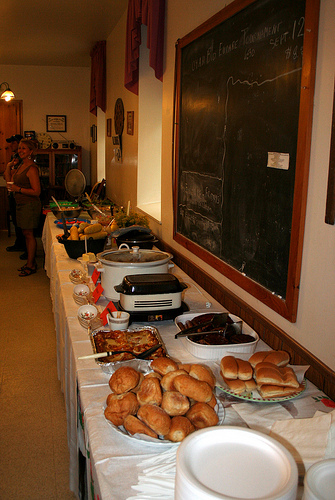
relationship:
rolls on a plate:
[104, 354, 221, 442] [102, 397, 226, 446]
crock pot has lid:
[94, 245, 173, 303] [102, 245, 170, 265]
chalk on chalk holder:
[239, 269, 286, 303] [171, 228, 285, 306]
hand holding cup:
[8, 182, 20, 193] [5, 179, 15, 194]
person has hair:
[7, 136, 42, 279] [17, 136, 33, 153]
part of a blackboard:
[227, 105, 242, 126] [169, 2, 321, 325]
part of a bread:
[183, 381, 199, 392] [102, 356, 221, 444]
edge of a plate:
[218, 386, 295, 404] [215, 365, 307, 402]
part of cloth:
[101, 439, 113, 451] [39, 208, 334, 500]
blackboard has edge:
[169, 2, 321, 325] [169, 32, 183, 244]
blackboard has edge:
[169, 2, 321, 325] [170, 227, 301, 324]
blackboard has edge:
[169, 2, 321, 325] [280, 1, 320, 323]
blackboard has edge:
[169, 2, 321, 325] [171, 1, 255, 50]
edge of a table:
[40, 208, 104, 498] [38, 199, 335, 499]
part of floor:
[24, 382, 46, 405] [2, 222, 72, 499]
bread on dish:
[102, 356, 221, 444] [105, 394, 226, 445]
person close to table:
[7, 136, 42, 279] [38, 199, 335, 499]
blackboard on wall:
[169, 2, 321, 325] [82, 1, 335, 406]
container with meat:
[171, 310, 261, 359] [179, 312, 254, 346]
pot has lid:
[93, 240, 177, 305] [102, 245, 170, 265]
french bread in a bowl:
[66, 220, 110, 242] [56, 232, 109, 257]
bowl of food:
[48, 204, 83, 219] [55, 205, 82, 212]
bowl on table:
[56, 232, 109, 257] [38, 199, 335, 499]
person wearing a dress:
[7, 136, 42, 279] [10, 162, 44, 233]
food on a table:
[55, 205, 82, 212] [38, 199, 335, 499]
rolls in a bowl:
[104, 354, 221, 442] [100, 396, 225, 447]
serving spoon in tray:
[76, 344, 162, 365] [85, 325, 173, 375]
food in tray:
[93, 330, 163, 360] [85, 325, 173, 375]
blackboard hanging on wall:
[169, 2, 321, 325] [82, 1, 335, 406]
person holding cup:
[7, 136, 42, 279] [5, 179, 15, 194]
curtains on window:
[121, 0, 167, 95] [135, 19, 165, 223]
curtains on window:
[85, 39, 109, 115] [92, 106, 110, 181]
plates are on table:
[171, 423, 298, 498] [38, 199, 335, 499]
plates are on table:
[302, 455, 334, 500] [38, 199, 335, 499]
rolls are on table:
[104, 354, 221, 442] [38, 199, 335, 499]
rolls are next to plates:
[104, 354, 221, 442] [171, 423, 298, 498]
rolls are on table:
[217, 347, 303, 401] [38, 199, 335, 499]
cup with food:
[106, 310, 131, 331] [114, 310, 127, 320]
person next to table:
[7, 136, 42, 281] [38, 199, 335, 499]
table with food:
[38, 199, 335, 499] [46, 195, 311, 445]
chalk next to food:
[239, 269, 286, 303] [46, 195, 311, 445]